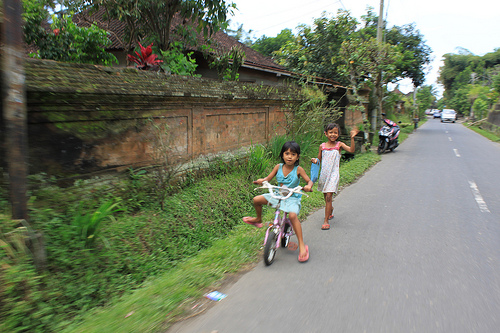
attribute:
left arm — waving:
[338, 124, 358, 155]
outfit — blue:
[249, 157, 327, 221]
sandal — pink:
[299, 243, 309, 261]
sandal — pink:
[242, 214, 262, 226]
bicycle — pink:
[253, 176, 324, 283]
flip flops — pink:
[241, 213, 313, 265]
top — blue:
[273, 162, 300, 198]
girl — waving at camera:
[319, 123, 359, 223]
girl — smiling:
[307, 118, 362, 234]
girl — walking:
[311, 123, 358, 230]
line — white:
[464, 173, 487, 228]